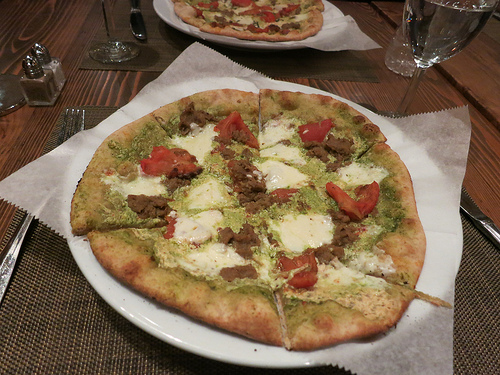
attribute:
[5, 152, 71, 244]
paper — wax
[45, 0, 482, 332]
table — wooden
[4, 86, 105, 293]
fork — shiny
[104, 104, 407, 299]
pizza — whole, gourmet, chucnk, slices, crusted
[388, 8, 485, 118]
water — glass, tall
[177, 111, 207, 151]
cheese — goat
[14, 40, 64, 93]
salt — small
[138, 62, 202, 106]
paper — wax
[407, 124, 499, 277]
knife — shiny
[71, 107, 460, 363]
plate — white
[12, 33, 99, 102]
shakers — salt, pepper